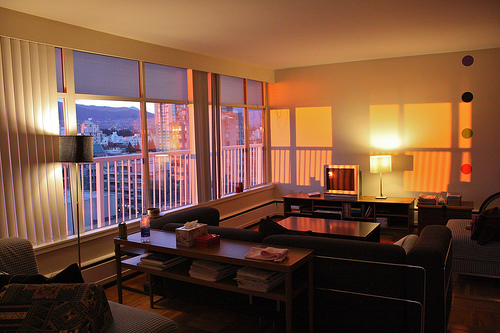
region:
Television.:
[320, 163, 363, 198]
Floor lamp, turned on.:
[56, 126, 98, 286]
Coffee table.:
[274, 211, 382, 243]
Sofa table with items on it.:
[107, 211, 316, 331]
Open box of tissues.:
[174, 221, 211, 246]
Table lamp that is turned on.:
[368, 151, 394, 200]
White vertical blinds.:
[4, 38, 69, 248]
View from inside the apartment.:
[53, 44, 270, 236]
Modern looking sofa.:
[140, 203, 455, 330]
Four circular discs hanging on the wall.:
[457, 49, 477, 180]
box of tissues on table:
[172, 216, 214, 256]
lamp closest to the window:
[43, 122, 115, 317]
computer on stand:
[306, 155, 377, 205]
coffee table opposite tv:
[272, 199, 385, 259]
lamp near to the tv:
[363, 145, 413, 218]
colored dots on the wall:
[448, 41, 480, 206]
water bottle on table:
[128, 205, 160, 262]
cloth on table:
[242, 235, 306, 278]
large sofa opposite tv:
[142, 199, 467, 331]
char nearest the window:
[2, 238, 194, 331]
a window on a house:
[74, 95, 142, 153]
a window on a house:
[72, 47, 147, 99]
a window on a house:
[141, 58, 192, 104]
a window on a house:
[219, 75, 245, 105]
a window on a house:
[243, 73, 263, 110]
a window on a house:
[145, 99, 188, 150]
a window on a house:
[104, 157, 150, 212]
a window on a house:
[154, 152, 190, 205]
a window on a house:
[213, 144, 247, 193]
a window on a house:
[247, 145, 267, 184]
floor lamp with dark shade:
[52, 131, 97, 285]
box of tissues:
[171, 216, 210, 249]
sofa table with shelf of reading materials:
[110, 216, 323, 332]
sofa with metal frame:
[325, 226, 456, 323]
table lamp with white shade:
[365, 146, 395, 204]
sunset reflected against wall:
[255, 94, 485, 204]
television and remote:
[302, 158, 365, 209]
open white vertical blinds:
[0, 48, 99, 243]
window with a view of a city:
[134, 52, 206, 217]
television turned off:
[317, 160, 365, 205]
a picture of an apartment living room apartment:
[1, 1, 498, 332]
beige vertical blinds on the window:
[1, 35, 72, 245]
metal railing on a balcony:
[92, 146, 191, 224]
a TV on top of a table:
[323, 163, 358, 195]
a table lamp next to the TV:
[369, 153, 391, 199]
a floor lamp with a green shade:
[58, 134, 93, 280]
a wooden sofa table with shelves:
[112, 227, 307, 330]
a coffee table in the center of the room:
[276, 211, 381, 243]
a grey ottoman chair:
[446, 216, 499, 278]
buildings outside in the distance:
[80, 118, 139, 153]